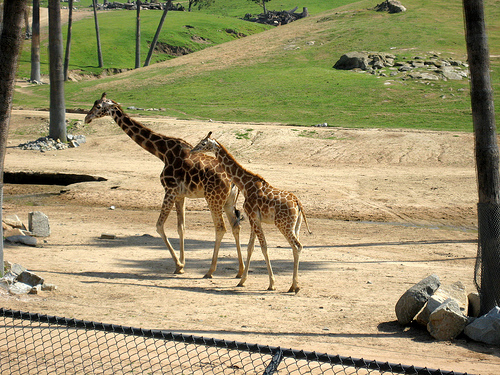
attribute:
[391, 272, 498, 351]
rocks — large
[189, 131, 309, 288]
giraffe — baby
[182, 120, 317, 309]
giraffe — smaller, not fuzzy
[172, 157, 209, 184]
spots — brown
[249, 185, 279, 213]
spots — brown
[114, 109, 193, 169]
spots — brown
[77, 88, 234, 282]
body — giraffe's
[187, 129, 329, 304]
body — giraffe's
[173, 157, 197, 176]
spots — brown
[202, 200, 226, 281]
leg — giraffe's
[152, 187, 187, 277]
leg — giraffe's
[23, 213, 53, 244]
rock — large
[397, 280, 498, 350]
rock — large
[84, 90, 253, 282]
giraffe — another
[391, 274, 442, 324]
rock — large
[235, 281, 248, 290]
hoof — cloven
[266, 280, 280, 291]
hoof — cloven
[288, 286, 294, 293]
hoof — cloven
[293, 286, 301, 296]
hoof — cloven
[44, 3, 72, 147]
trunk — tree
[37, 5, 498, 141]
field — sloped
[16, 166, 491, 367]
surface — dirt